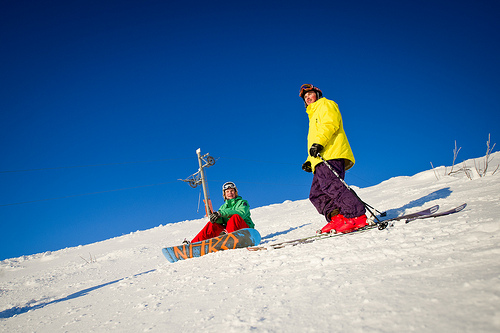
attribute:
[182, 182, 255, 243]
boy — sitting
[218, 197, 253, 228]
jacket — green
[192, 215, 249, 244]
pants — red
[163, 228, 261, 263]
snowboard — blue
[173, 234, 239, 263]
letters — orange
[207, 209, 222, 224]
gloves — leather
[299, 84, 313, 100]
googles — orange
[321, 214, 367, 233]
boots — red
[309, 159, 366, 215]
pants — purple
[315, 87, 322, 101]
helmet — black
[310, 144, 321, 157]
glove — black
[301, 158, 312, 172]
glove — black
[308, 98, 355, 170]
jecket — yellow